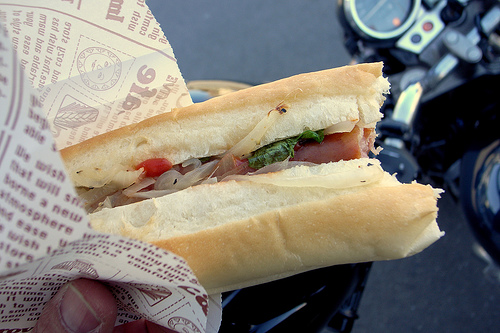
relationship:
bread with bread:
[58, 61, 449, 298] [51, 51, 460, 304]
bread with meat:
[58, 61, 449, 298] [210, 104, 402, 194]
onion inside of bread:
[81, 156, 217, 205] [58, 61, 449, 298]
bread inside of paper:
[58, 61, 449, 298] [1, 1, 233, 327]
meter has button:
[327, 0, 434, 47] [422, 21, 435, 33]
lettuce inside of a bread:
[237, 121, 331, 173] [58, 61, 449, 298]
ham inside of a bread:
[218, 109, 387, 179] [58, 61, 449, 298]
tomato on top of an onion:
[129, 144, 191, 183] [75, 152, 240, 218]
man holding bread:
[29, 277, 118, 332] [58, 61, 449, 298]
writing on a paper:
[5, 133, 74, 256] [1, 1, 233, 327]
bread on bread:
[58, 61, 449, 298] [51, 51, 460, 304]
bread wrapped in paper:
[58, 61, 449, 298] [1, 1, 233, 327]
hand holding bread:
[32, 279, 122, 332] [58, 61, 449, 298]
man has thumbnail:
[29, 277, 118, 332] [57, 281, 102, 332]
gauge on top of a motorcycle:
[347, 3, 429, 38] [331, 0, 497, 322]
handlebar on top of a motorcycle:
[381, 47, 428, 183] [331, 0, 497, 322]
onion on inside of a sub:
[81, 156, 217, 205] [45, 61, 450, 275]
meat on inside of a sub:
[210, 104, 402, 194] [45, 61, 450, 275]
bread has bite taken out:
[58, 61, 449, 298] [344, 33, 456, 280]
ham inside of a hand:
[235, 126, 383, 175] [5, 238, 234, 332]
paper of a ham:
[1, 1, 233, 327] [235, 126, 383, 175]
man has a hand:
[10, 260, 207, 331] [32, 279, 122, 332]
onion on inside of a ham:
[81, 156, 217, 205] [235, 126, 383, 175]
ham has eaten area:
[235, 126, 383, 175] [357, 21, 451, 266]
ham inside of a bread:
[235, 126, 383, 175] [58, 61, 449, 298]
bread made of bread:
[58, 61, 449, 298] [51, 51, 460, 304]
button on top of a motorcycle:
[422, 21, 435, 33] [331, 0, 497, 322]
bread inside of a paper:
[58, 61, 449, 298] [1, 1, 233, 327]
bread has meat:
[58, 61, 449, 298] [210, 104, 402, 194]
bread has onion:
[58, 61, 449, 298] [81, 156, 217, 205]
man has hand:
[29, 277, 118, 332] [32, 279, 122, 332]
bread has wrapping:
[58, 61, 449, 298] [1, 4, 237, 330]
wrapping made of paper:
[1, 4, 237, 330] [1, 1, 233, 327]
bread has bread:
[58, 61, 449, 298] [58, 61, 449, 298]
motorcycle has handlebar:
[331, 0, 497, 322] [376, 71, 427, 179]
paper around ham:
[1, 1, 233, 327] [235, 126, 383, 175]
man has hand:
[29, 277, 118, 332] [5, 238, 234, 332]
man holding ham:
[29, 277, 118, 332] [235, 126, 383, 175]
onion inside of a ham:
[81, 156, 217, 205] [235, 126, 383, 175]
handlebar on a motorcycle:
[376, 71, 427, 179] [331, 0, 497, 322]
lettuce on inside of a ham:
[237, 121, 331, 173] [235, 126, 383, 175]